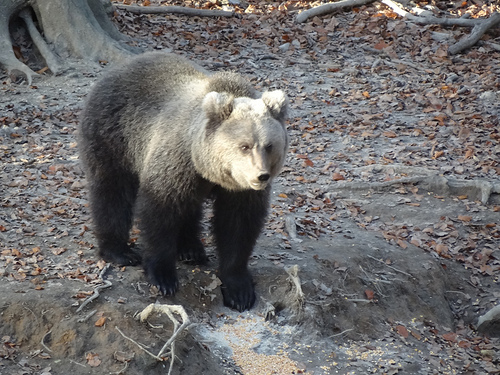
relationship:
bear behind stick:
[75, 51, 298, 310] [137, 304, 192, 373]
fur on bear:
[215, 75, 251, 95] [75, 51, 298, 310]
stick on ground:
[137, 304, 192, 373] [1, 296, 216, 370]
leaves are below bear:
[145, 2, 307, 52] [75, 51, 298, 310]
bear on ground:
[75, 51, 298, 310] [1, 296, 216, 370]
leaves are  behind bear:
[145, 2, 307, 52] [75, 51, 298, 310]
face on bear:
[225, 123, 279, 192] [75, 51, 298, 310]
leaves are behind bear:
[145, 2, 307, 52] [75, 51, 298, 310]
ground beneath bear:
[1, 296, 216, 370] [75, 51, 298, 310]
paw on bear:
[216, 267, 260, 313] [75, 51, 298, 310]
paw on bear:
[143, 249, 182, 295] [75, 51, 298, 310]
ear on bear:
[205, 93, 230, 123] [75, 51, 298, 310]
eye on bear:
[238, 146, 252, 151] [75, 51, 298, 310]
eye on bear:
[265, 142, 275, 154] [75, 51, 298, 310]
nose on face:
[258, 171, 270, 186] [225, 123, 279, 192]